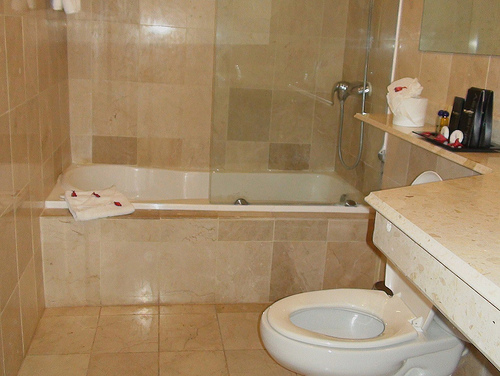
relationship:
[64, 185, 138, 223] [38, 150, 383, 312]
towel on side of tub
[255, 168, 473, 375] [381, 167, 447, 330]
toilet has a lid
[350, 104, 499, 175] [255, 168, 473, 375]
shelf above toilet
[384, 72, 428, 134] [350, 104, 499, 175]
toilet paper on shelf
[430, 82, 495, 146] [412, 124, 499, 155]
toiletries are on tray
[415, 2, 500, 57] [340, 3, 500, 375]
mirror on wall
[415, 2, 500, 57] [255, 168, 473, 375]
mirror above toilet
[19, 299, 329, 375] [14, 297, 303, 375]
tile on floor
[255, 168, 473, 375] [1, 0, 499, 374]
toilet in bathroom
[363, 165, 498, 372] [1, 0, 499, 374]
counter in bathroom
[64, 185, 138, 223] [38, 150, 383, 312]
towel on edge of tub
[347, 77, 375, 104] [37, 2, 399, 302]
faucet in shower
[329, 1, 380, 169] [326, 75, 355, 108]
hose connected to shower head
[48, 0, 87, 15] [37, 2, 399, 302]
towel hanging in shower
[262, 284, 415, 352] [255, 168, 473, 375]
seat on toilet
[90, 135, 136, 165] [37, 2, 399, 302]
tiles in shower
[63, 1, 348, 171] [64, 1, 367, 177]
tiles are on wall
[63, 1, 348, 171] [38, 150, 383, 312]
tiles are behind tub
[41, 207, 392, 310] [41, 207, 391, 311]
tile on exterior of the tub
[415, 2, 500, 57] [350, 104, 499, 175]
mirror above counter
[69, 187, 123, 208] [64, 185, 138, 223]
adornments are on towel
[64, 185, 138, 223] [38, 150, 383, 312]
towel laying on tub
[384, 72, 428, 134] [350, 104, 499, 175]
toilet paper sitting on counter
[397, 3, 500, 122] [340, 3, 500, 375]
section of wall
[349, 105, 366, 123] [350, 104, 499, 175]
edge of shelf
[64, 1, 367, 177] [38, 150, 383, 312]
wall behind tub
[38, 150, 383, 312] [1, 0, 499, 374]
tub in bathroom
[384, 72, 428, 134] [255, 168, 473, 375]
toilet paper above toilet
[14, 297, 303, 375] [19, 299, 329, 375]
floor made of tile